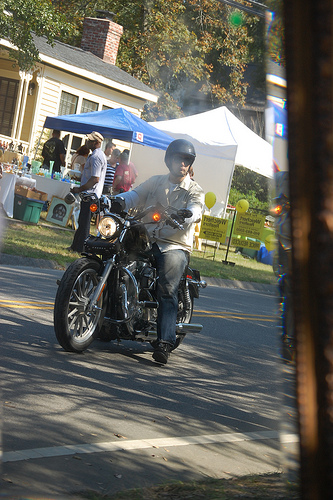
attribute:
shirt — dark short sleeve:
[104, 159, 118, 187]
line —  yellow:
[0, 299, 281, 322]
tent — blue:
[43, 104, 179, 159]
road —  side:
[11, 253, 277, 293]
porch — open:
[0, 58, 40, 159]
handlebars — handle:
[60, 181, 189, 235]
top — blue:
[36, 93, 186, 155]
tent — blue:
[26, 88, 190, 241]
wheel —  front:
[51, 256, 109, 353]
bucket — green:
[15, 196, 47, 223]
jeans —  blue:
[151, 250, 190, 346]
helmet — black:
[163, 137, 195, 166]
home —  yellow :
[1, 8, 159, 185]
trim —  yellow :
[0, 62, 42, 169]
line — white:
[2, 435, 266, 455]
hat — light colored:
[84, 129, 105, 146]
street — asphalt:
[11, 267, 284, 395]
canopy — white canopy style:
[161, 99, 274, 172]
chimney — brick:
[75, 11, 125, 54]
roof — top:
[37, 43, 141, 90]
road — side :
[0, 262, 296, 435]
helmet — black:
[164, 138, 194, 177]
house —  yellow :
[0, 16, 161, 170]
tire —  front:
[56, 250, 108, 352]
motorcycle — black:
[51, 179, 207, 364]